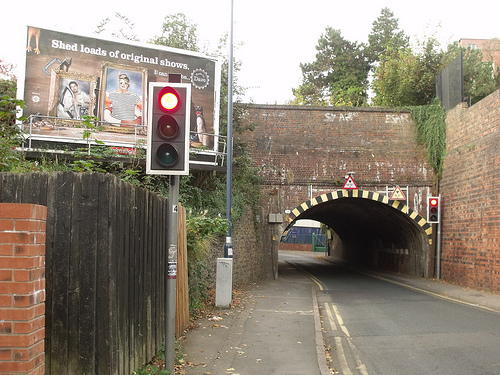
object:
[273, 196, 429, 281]
tunnel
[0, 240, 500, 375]
street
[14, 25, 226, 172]
billboard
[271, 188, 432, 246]
lines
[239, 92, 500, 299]
wall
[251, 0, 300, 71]
sky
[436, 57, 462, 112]
fence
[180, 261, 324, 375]
sidewalk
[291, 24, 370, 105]
trees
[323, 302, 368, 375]
lines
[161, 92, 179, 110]
light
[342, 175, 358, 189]
yield sign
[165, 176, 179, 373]
pole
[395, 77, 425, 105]
leaves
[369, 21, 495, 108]
tree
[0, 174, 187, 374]
fence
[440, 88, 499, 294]
brick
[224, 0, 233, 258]
pole